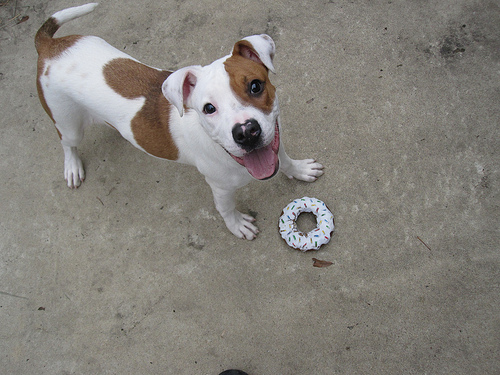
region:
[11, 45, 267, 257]
Brown and white puppy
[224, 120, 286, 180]
dog with his mouth open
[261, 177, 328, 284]
toy in front of dog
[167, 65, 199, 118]
puppy with droppy ears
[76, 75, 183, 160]
dog with brown spots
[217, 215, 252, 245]
dog with white paws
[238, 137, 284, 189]
dog with a pink tongue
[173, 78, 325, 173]
puppy looking upwards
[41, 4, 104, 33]
Dog with a white tail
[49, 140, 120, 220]
dog with a white paw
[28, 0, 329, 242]
White and brown dog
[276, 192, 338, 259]
A dog treat on the ground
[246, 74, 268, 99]
Left eye of the dog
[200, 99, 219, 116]
Right eye of the dog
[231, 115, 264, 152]
The nose of the dog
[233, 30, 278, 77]
The left ear of the dog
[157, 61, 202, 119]
The right ear of the dog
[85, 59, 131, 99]
Brown and white dog fur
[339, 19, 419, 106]
Part of the ground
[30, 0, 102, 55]
The tail of the dog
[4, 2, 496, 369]
cement surface of ground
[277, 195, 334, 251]
donut laying on ground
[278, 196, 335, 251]
white frosting on donut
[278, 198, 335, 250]
sprinkles on white frosting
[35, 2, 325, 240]
brown and white dog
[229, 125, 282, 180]
tongue in open mouth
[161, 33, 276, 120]
folded ears on dog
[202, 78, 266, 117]
dark brown dog eyes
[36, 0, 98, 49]
brown and white dog tail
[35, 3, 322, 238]
brown and white fur on dog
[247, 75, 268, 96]
eye of a dog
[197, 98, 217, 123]
eye of a dog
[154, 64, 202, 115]
ear of a dog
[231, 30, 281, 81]
ear of a dog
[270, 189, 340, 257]
toy shaped like a donut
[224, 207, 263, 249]
paw of a dog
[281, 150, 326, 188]
paw of a dog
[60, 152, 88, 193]
paw of a dog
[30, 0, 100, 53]
tail of a dog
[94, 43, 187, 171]
brown spot on a dog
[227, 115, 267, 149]
black nose of a dog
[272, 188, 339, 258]
dog toy shaped like a donut